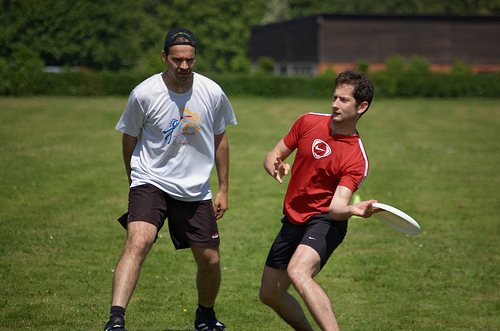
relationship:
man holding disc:
[250, 65, 431, 328] [362, 196, 430, 244]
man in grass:
[250, 65, 431, 328] [1, 96, 500, 329]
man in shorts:
[250, 65, 431, 328] [265, 209, 348, 272]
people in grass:
[83, 23, 436, 330] [1, 96, 500, 329]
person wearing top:
[104, 16, 253, 328] [117, 67, 241, 206]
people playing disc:
[83, 23, 436, 330] [362, 196, 430, 244]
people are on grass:
[83, 23, 436, 330] [1, 96, 500, 329]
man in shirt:
[250, 65, 431, 328] [278, 108, 375, 220]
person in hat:
[104, 16, 253, 328] [154, 25, 204, 46]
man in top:
[250, 65, 431, 328] [117, 67, 241, 206]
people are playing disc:
[83, 23, 436, 330] [362, 196, 430, 244]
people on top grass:
[83, 23, 436, 330] [1, 96, 500, 329]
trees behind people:
[1, 1, 301, 88] [83, 23, 436, 330]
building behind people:
[247, 5, 499, 85] [83, 23, 436, 330]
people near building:
[83, 23, 436, 330] [247, 5, 499, 85]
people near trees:
[83, 23, 436, 330] [1, 1, 301, 88]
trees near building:
[1, 1, 301, 88] [247, 5, 499, 85]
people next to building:
[83, 23, 436, 330] [247, 5, 499, 85]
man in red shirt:
[250, 65, 431, 328] [278, 108, 375, 220]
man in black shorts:
[250, 65, 431, 328] [265, 209, 348, 272]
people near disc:
[83, 23, 436, 330] [362, 196, 430, 244]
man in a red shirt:
[250, 65, 431, 328] [278, 108, 375, 220]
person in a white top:
[104, 16, 253, 328] [117, 67, 241, 206]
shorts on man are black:
[265, 209, 348, 272] [307, 220, 341, 240]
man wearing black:
[250, 65, 431, 328] [307, 220, 341, 240]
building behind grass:
[247, 5, 499, 85] [1, 96, 500, 329]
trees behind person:
[1, 1, 301, 88] [104, 16, 253, 328]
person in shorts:
[104, 16, 253, 328] [265, 209, 348, 272]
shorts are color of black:
[265, 209, 348, 272] [307, 220, 341, 240]